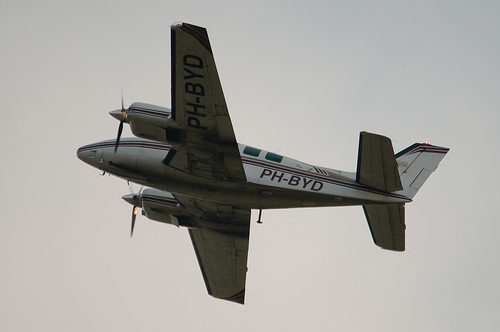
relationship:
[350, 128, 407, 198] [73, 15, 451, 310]
wing on plane